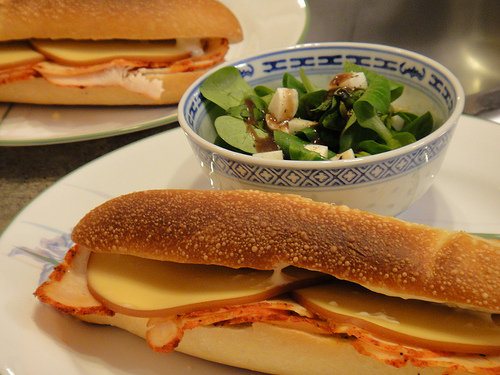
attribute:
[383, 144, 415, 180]
design — blue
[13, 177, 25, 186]
countertop — brown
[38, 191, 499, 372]
sandwich — toasted, DELI PREPARED, turkey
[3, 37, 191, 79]
deli meat — FRESH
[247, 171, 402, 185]
design — blue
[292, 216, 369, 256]
bread — brown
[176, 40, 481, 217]
bowl — blue, white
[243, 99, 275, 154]
dressing — brown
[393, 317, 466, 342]
cheese — piece, here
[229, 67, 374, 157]
dressing — brown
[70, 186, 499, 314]
bread — brown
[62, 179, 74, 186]
plate — white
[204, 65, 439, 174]
salad — small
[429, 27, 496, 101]
stainless steel — piece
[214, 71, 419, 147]
salad — fresh, green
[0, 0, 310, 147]
plate — green rimmed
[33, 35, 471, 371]
lunch — meal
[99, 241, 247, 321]
cheese — light yellow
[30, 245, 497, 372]
meat — turkey